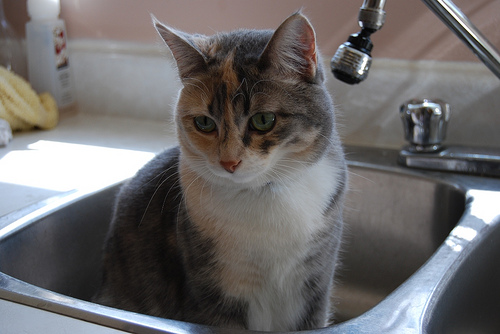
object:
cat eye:
[249, 108, 276, 136]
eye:
[248, 110, 278, 133]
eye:
[193, 112, 216, 134]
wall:
[74, 4, 151, 123]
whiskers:
[266, 149, 352, 166]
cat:
[87, 10, 349, 332]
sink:
[2, 160, 470, 333]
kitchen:
[1, 2, 499, 331]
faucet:
[332, 0, 500, 173]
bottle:
[23, 0, 78, 107]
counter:
[3, 115, 167, 186]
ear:
[257, 10, 319, 79]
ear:
[153, 12, 212, 79]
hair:
[282, 35, 307, 82]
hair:
[167, 41, 194, 68]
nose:
[219, 159, 245, 174]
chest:
[186, 160, 328, 289]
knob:
[397, 100, 449, 156]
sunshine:
[7, 137, 159, 192]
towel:
[2, 66, 63, 130]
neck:
[194, 164, 330, 199]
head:
[144, 17, 337, 179]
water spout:
[330, 25, 379, 85]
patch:
[305, 235, 332, 276]